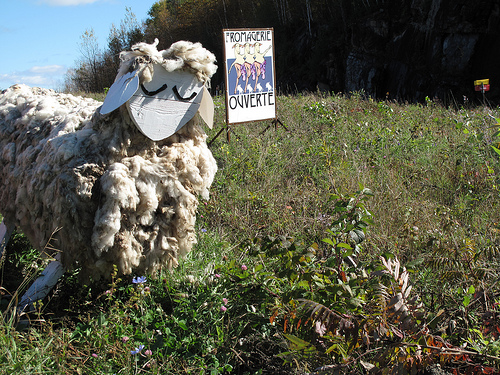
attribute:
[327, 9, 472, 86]
trees — green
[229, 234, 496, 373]
vegetation — green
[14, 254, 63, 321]
legs — wooden, white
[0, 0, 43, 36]
sky — white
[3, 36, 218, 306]
lamb — fake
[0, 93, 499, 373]
vegetation — green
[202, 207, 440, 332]
vegetation — green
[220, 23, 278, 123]
sign — white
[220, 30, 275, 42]
fromagerie — written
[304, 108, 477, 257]
bush — small, green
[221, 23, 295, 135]
signboard — white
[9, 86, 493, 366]
field — grassy, green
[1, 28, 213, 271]
wool — gray, white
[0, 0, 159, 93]
sky — blue, white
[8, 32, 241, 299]
lamb — fake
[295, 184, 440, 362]
bush — green, brown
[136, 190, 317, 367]
bush — brown, green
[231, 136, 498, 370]
vegetation — green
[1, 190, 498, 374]
growth — weed, grassy, bushy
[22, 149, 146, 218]
fur — thick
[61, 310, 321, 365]
vegetation — green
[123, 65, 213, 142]
face — cardboard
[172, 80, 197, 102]
eye — black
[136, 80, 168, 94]
eye — black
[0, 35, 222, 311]
sheep — white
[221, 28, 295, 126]
signboard — yellow, red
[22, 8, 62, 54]
sky — blue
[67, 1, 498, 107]
trees — thick, dark green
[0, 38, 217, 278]
sheep — faux, fake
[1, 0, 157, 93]
clouds — small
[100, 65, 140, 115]
ear — white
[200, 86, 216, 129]
ear — white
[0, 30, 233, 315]
body — covered